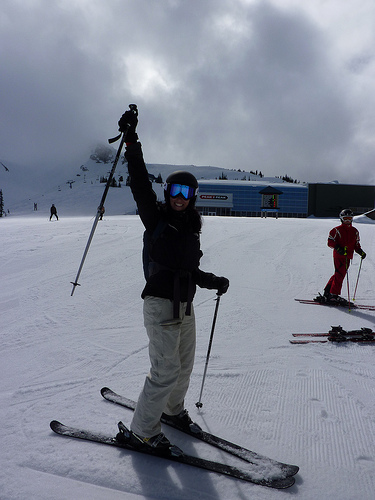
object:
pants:
[129, 293, 197, 442]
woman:
[119, 111, 230, 454]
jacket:
[123, 143, 217, 304]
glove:
[117, 110, 138, 134]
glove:
[217, 277, 228, 295]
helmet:
[164, 170, 199, 208]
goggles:
[167, 184, 196, 200]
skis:
[50, 419, 302, 487]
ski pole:
[68, 103, 139, 295]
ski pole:
[193, 281, 222, 410]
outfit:
[325, 226, 362, 298]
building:
[196, 180, 308, 215]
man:
[323, 210, 366, 302]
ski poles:
[352, 255, 363, 302]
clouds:
[2, 2, 374, 184]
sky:
[0, 2, 374, 186]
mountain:
[0, 139, 293, 217]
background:
[3, 133, 372, 213]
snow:
[231, 451, 287, 485]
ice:
[1, 216, 370, 498]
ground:
[1, 213, 374, 497]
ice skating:
[293, 209, 374, 314]